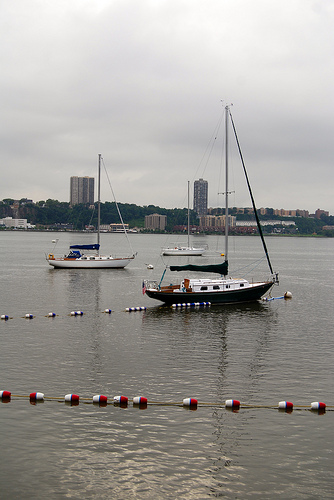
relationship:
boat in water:
[146, 104, 277, 305] [3, 230, 332, 498]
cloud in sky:
[102, 17, 246, 97] [0, 1, 330, 214]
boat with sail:
[146, 104, 277, 305] [170, 261, 232, 278]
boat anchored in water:
[146, 104, 277, 305] [3, 230, 332, 498]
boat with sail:
[52, 152, 135, 271] [70, 244, 101, 251]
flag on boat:
[141, 279, 150, 296] [146, 104, 277, 305]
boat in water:
[52, 152, 135, 271] [3, 230, 332, 498]